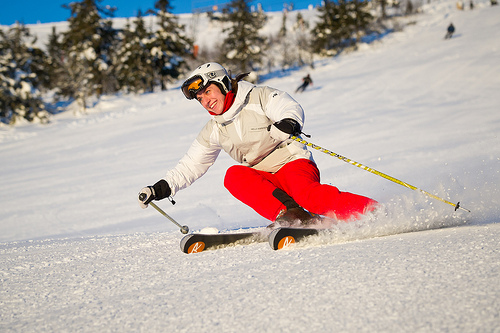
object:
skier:
[129, 54, 399, 255]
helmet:
[177, 57, 240, 101]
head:
[183, 60, 234, 116]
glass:
[181, 78, 204, 90]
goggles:
[180, 72, 209, 100]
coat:
[158, 79, 317, 197]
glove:
[134, 179, 174, 208]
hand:
[138, 176, 174, 208]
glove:
[264, 115, 306, 144]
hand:
[267, 116, 303, 141]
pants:
[221, 157, 384, 226]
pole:
[147, 202, 192, 237]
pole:
[296, 135, 462, 209]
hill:
[376, 7, 498, 108]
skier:
[442, 20, 457, 43]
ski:
[177, 230, 264, 254]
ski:
[266, 225, 326, 250]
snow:
[388, 196, 499, 225]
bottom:
[268, 226, 386, 250]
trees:
[53, 0, 109, 117]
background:
[0, 1, 499, 125]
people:
[293, 71, 318, 94]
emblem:
[277, 234, 298, 251]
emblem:
[188, 240, 210, 252]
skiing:
[104, 58, 497, 261]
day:
[4, 0, 499, 333]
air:
[5, 0, 494, 289]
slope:
[352, 45, 499, 157]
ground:
[0, 240, 499, 321]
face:
[197, 83, 233, 115]